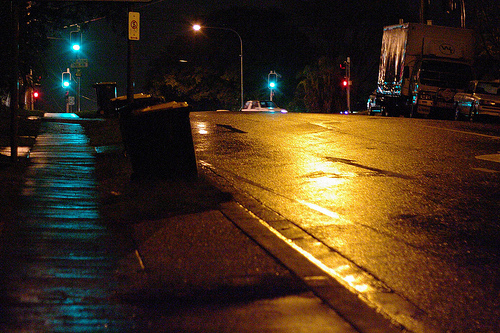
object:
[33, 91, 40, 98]
light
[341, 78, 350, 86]
light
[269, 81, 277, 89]
light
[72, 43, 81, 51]
light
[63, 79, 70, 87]
light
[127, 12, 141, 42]
sign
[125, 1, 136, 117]
post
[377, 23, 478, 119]
truck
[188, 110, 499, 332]
street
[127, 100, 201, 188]
garbage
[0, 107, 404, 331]
side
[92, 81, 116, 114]
garbage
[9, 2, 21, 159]
pole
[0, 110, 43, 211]
yard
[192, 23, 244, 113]
streetlight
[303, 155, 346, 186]
reflection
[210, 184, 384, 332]
curb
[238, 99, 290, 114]
car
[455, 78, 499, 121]
car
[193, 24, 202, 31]
light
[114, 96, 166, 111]
lid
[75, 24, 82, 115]
post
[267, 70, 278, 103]
post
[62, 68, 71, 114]
post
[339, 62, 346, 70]
signal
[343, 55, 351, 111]
post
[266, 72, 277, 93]
signal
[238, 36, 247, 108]
pole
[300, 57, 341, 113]
tree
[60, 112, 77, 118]
reflection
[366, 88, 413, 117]
car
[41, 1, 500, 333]
night